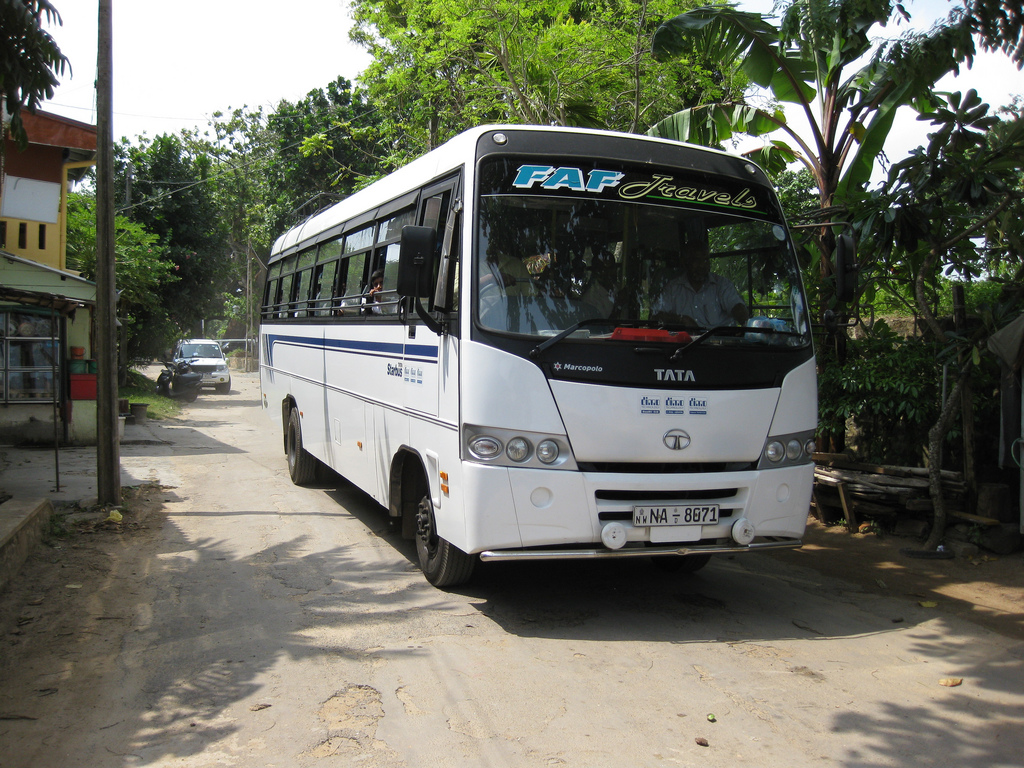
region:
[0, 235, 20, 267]
a window on a building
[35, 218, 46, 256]
a window on a building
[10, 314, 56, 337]
a window on a building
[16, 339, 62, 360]
a window on a building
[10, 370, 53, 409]
a window on a building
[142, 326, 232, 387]
a car on a street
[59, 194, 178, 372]
a tree in a field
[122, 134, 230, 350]
a tree in a field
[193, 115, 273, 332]
a tree in a field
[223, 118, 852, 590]
A white bus at a curb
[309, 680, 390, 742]
A pothole in a road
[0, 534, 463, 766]
The shadow of a tree on a street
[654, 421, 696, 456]
A silver insignia on a bus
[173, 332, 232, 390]
A white car parked on a street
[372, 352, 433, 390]
Blue letters on the side of a bus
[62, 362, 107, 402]
A red bin outside a building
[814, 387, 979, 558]
A wooden bench on the side of a street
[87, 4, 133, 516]
A tall skinny tree trunk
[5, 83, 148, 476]
A building on the left side of the street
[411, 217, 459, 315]
window on the bus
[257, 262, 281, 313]
window on the bus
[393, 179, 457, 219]
window on the bus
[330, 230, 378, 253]
window on the bus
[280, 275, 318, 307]
window on the bus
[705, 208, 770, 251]
window on the bus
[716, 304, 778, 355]
window on the bus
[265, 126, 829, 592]
A bus on a road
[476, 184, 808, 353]
Windshield on a bus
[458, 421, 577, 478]
Head lights on a bus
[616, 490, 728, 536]
License plate on a bus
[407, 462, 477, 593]
Wheel on a bus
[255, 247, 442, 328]
Windows on a bus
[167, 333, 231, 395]
A truck on a road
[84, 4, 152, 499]
A telephone pole beside a road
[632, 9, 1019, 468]
A tree beside a bus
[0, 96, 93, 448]
A building beside a road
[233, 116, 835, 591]
a big white bus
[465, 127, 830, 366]
windshield of a bus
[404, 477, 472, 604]
the front tires of a bus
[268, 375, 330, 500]
the rear tire of a bus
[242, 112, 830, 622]
white and black bus on street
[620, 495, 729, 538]
white and black license plate on front of bus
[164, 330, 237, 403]
white car driving behind bus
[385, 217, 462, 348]
rear view mirror on side of bus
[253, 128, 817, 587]
a small transport bus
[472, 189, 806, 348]
a windshield on a bus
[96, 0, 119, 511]
a wooden power line pole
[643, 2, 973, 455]
a palm tree near the road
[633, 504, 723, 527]
a license plate on a bus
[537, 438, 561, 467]
a headlight on a bus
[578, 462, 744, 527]
a grate on the front of a bus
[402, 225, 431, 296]
a mirror on the side of a bus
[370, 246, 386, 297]
an open window on a bus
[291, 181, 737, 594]
the bus is white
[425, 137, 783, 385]
this is a windshield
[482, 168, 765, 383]
the windshield is reflective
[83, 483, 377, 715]
the street is partially shaded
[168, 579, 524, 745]
the street is paved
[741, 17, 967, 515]
this is a palm tree